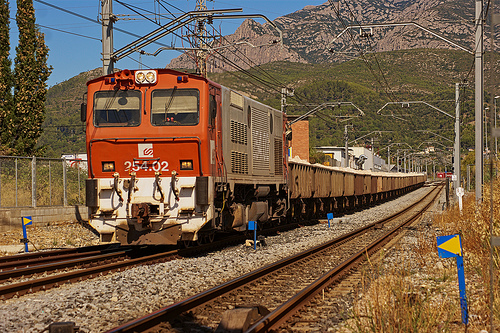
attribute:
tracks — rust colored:
[6, 160, 431, 307]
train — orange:
[80, 63, 430, 255]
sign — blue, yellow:
[433, 226, 471, 330]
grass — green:
[39, 51, 496, 160]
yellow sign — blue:
[425, 222, 481, 331]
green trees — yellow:
[0, 1, 54, 161]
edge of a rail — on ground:
[413, 178, 449, 230]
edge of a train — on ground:
[358, 167, 433, 191]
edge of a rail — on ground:
[1, 240, 80, 305]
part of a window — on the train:
[167, 83, 201, 134]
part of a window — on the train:
[92, 87, 119, 133]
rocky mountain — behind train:
[189, 6, 374, 79]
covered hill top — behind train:
[126, 9, 500, 149]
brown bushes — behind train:
[174, 11, 421, 70]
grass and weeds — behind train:
[356, 195, 499, 331]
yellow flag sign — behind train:
[433, 225, 484, 330]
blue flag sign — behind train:
[245, 216, 264, 255]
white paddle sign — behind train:
[454, 183, 470, 223]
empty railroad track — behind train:
[148, 254, 346, 331]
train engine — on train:
[72, 61, 294, 257]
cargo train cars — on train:
[283, 155, 435, 220]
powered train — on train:
[75, 66, 439, 259]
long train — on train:
[79, 68, 434, 256]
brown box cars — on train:
[284, 145, 451, 224]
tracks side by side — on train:
[262, 103, 445, 240]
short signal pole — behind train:
[274, 89, 370, 241]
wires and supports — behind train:
[182, 7, 424, 116]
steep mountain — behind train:
[42, 52, 109, 151]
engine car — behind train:
[71, 64, 299, 243]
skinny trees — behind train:
[0, 3, 60, 160]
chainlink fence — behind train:
[0, 149, 92, 206]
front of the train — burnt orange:
[83, 64, 216, 242]